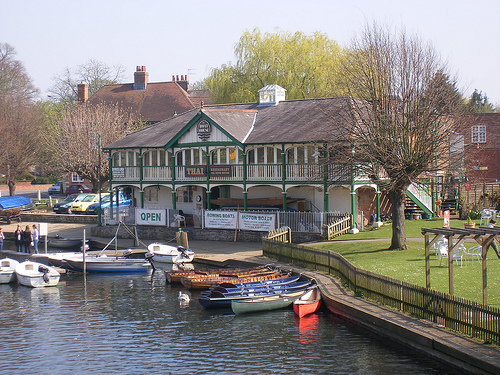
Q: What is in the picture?
A: Boats.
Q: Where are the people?
A: A Lodge.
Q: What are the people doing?
A: Standing on the deck.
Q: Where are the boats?
A: Lake.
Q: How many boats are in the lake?
A: Ten.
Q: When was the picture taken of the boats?
A: Daytime.